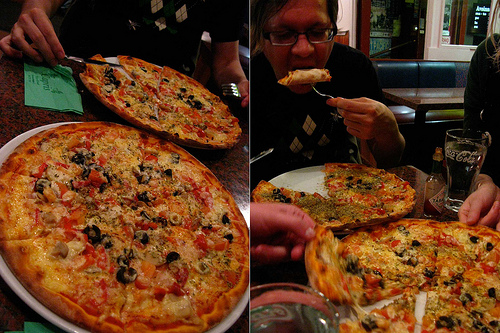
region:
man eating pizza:
[279, 64, 315, 77]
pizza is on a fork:
[296, 72, 336, 96]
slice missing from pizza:
[299, 165, 341, 209]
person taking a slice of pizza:
[455, 212, 481, 227]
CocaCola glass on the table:
[426, 140, 476, 196]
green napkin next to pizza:
[25, 72, 79, 120]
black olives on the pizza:
[104, 262, 131, 284]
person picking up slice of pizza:
[287, 212, 339, 266]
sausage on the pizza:
[55, 231, 81, 260]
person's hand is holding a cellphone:
[217, 71, 261, 109]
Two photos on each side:
[3, 3, 498, 330]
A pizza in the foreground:
[0, 119, 245, 331]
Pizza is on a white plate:
[3, 118, 249, 329]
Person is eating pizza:
[256, 0, 349, 99]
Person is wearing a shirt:
[250, 38, 395, 168]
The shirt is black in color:
[250, 40, 391, 170]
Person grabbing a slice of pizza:
[250, 194, 420, 311]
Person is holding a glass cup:
[437, 115, 499, 213]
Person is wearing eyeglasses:
[260, 18, 339, 55]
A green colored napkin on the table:
[12, 43, 89, 121]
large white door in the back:
[401, 19, 454, 60]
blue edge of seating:
[395, 51, 452, 74]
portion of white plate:
[271, 163, 328, 190]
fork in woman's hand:
[296, 77, 348, 109]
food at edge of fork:
[279, 64, 334, 96]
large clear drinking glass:
[425, 108, 489, 208]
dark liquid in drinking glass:
[442, 145, 479, 205]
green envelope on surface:
[16, 50, 85, 115]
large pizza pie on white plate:
[31, 120, 218, 326]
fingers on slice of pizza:
[264, 193, 340, 270]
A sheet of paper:
[15, 67, 85, 114]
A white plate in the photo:
[270, 167, 325, 194]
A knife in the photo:
[62, 49, 96, 74]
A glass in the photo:
[442, 125, 489, 210]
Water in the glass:
[253, 301, 330, 331]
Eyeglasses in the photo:
[268, 20, 329, 47]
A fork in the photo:
[313, 79, 340, 108]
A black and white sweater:
[257, 49, 381, 154]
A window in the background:
[362, 0, 482, 65]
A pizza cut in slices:
[325, 215, 476, 328]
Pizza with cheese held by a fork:
[268, 63, 343, 107]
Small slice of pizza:
[120, 44, 165, 93]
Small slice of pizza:
[401, 283, 420, 329]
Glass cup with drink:
[434, 111, 479, 231]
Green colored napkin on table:
[24, 63, 84, 120]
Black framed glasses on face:
[258, 18, 342, 55]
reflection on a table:
[402, 84, 456, 102]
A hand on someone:
[5, 10, 80, 69]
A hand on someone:
[324, 85, 390, 150]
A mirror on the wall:
[440, 3, 483, 55]